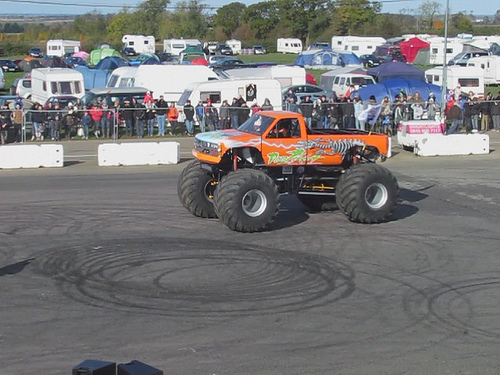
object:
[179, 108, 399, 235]
monster truck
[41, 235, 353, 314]
track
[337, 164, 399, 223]
tires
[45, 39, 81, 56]
campers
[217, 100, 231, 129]
spectators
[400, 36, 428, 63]
tent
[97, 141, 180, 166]
barricade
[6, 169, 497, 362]
arena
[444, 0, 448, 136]
pole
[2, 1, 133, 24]
sky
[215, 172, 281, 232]
tire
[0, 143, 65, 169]
block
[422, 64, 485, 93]
trailer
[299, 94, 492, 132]
crowd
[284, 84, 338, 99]
car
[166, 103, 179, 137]
van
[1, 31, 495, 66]
lot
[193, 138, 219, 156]
grill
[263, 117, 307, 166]
door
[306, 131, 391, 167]
bed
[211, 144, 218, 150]
headlight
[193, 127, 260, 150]
hood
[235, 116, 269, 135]
windshield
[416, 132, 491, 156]
barrier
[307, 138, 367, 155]
skeleton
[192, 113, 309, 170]
cab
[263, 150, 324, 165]
writing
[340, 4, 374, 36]
trees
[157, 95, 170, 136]
person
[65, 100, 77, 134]
person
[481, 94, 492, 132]
person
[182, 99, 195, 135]
he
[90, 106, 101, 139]
she